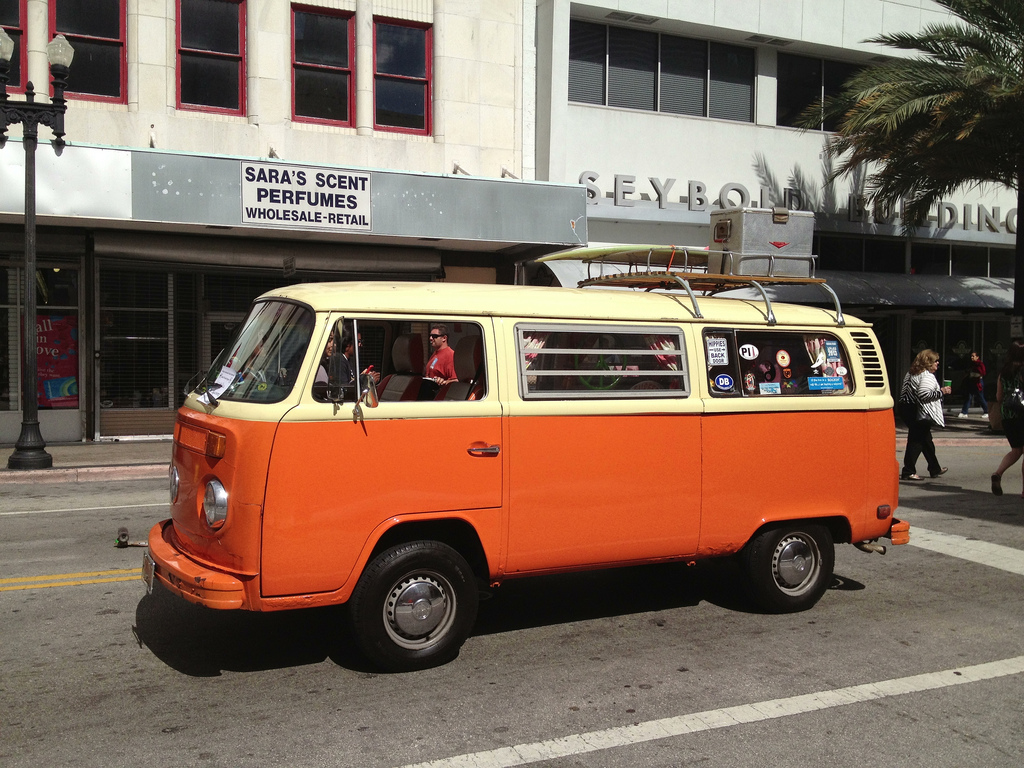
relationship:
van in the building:
[114, 246, 909, 672] [540, 0, 1020, 434]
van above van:
[114, 246, 909, 672] [114, 246, 909, 672]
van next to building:
[114, 246, 909, 672] [540, 0, 1020, 434]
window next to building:
[570, 20, 748, 109] [540, 0, 1020, 434]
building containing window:
[540, 0, 1020, 434] [675, 11, 701, 113]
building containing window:
[697, 33, 780, 135] [697, 33, 780, 135]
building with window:
[540, 0, 1020, 434] [762, 7, 802, 137]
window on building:
[386, 2, 425, 127] [389, 2, 425, 127]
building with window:
[0, 0, 589, 450] [298, 21, 336, 139]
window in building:
[204, 8, 244, 98] [209, 13, 239, 108]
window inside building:
[137, 263, 182, 514] [137, 263, 182, 514]